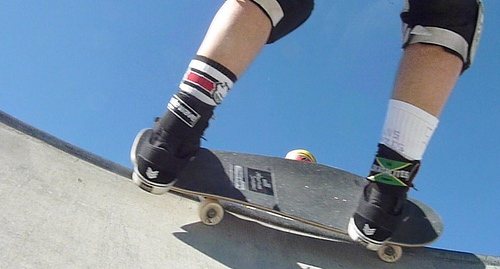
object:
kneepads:
[225, 0, 317, 44]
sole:
[131, 127, 179, 194]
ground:
[417, 147, 457, 178]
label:
[229, 160, 273, 195]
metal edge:
[0, 111, 136, 182]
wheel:
[375, 243, 401, 262]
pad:
[394, 0, 485, 68]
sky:
[1, 1, 498, 257]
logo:
[211, 80, 232, 102]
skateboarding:
[0, 0, 500, 269]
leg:
[363, 0, 485, 207]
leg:
[163, 3, 290, 144]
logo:
[359, 225, 380, 236]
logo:
[148, 169, 160, 179]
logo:
[214, 78, 228, 99]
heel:
[345, 220, 385, 250]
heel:
[128, 163, 170, 194]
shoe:
[126, 125, 178, 195]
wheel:
[200, 205, 225, 224]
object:
[284, 146, 316, 163]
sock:
[166, 54, 236, 136]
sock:
[379, 98, 439, 163]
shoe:
[341, 187, 411, 252]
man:
[124, 0, 484, 247]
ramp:
[1, 114, 500, 269]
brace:
[351, 136, 421, 216]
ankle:
[350, 142, 423, 232]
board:
[133, 150, 445, 262]